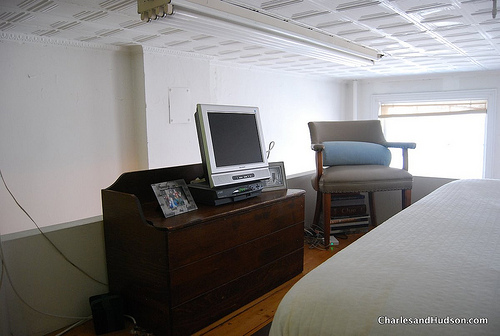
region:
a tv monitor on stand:
[192, 85, 290, 190]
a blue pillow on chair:
[315, 128, 402, 178]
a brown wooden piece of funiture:
[93, 174, 343, 334]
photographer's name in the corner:
[367, 310, 498, 335]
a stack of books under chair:
[321, 192, 373, 243]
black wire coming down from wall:
[4, 177, 124, 334]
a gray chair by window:
[306, 100, 448, 223]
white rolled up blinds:
[379, 100, 491, 120]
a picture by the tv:
[150, 167, 210, 227]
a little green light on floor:
[330, 238, 337, 248]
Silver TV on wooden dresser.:
[190, 102, 272, 182]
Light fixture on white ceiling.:
[138, 0, 377, 65]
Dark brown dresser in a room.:
[101, 162, 303, 332]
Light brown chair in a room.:
[307, 117, 417, 246]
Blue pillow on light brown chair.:
[317, 140, 391, 166]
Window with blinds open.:
[377, 99, 485, 180]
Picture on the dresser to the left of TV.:
[149, 178, 198, 216]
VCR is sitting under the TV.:
[186, 178, 261, 206]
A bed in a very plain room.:
[271, 179, 498, 334]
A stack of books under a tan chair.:
[330, 193, 371, 237]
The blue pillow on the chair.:
[318, 140, 394, 164]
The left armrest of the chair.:
[308, 137, 324, 172]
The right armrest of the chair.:
[387, 134, 414, 161]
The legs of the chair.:
[310, 186, 422, 240]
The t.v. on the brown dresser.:
[202, 100, 267, 180]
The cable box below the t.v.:
[202, 183, 261, 200]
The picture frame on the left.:
[155, 182, 195, 217]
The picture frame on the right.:
[265, 157, 287, 190]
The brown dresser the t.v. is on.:
[111, 177, 314, 332]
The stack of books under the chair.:
[328, 186, 367, 241]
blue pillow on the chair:
[316, 138, 393, 168]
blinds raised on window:
[378, 100, 488, 120]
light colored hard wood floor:
[46, 228, 363, 334]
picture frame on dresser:
[258, 160, 289, 191]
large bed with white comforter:
[265, 176, 499, 334]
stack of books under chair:
[317, 187, 372, 235]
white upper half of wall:
[0, 40, 499, 237]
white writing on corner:
[376, 314, 489, 326]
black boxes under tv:
[184, 179, 268, 206]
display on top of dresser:
[99, 100, 309, 335]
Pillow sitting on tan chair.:
[318, 133, 402, 165]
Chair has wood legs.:
[306, 191, 418, 227]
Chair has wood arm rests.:
[303, 129, 428, 164]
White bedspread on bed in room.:
[401, 200, 451, 307]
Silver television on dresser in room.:
[196, 100, 280, 197]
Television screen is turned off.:
[211, 115, 271, 166]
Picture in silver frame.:
[151, 183, 210, 228]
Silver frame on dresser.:
[149, 163, 208, 250]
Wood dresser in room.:
[124, 208, 325, 310]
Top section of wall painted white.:
[3, 75, 107, 185]